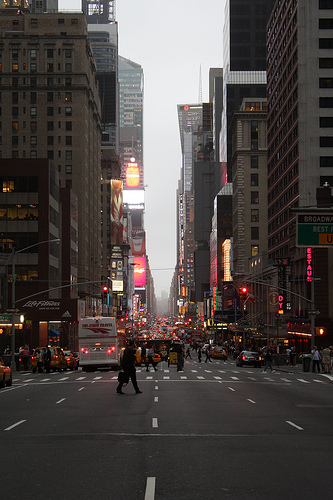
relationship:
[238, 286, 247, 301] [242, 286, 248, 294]
street light with street light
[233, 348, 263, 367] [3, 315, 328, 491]
car on street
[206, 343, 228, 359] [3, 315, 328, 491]
car on street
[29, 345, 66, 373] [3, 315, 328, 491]
car on street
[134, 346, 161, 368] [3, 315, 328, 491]
taxi cab on street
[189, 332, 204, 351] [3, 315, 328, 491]
car on street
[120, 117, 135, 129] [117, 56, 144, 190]
window on building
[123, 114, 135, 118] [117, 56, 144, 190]
window on building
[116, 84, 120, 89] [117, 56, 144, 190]
window on building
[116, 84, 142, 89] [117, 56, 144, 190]
window on building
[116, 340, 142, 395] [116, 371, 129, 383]
person carrying bag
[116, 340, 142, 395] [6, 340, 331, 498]
person crossing street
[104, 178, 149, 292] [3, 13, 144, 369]
billboards on side of buildings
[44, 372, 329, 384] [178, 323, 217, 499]
white marks on street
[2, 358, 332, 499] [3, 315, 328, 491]
lines on street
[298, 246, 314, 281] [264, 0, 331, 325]
sign on building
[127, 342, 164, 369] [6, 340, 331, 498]
taxi cab on street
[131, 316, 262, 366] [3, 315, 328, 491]
traffic in street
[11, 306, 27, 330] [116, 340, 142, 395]
traffic signal for person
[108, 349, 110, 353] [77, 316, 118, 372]
tail light on bus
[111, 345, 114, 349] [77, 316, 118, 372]
tail light on bus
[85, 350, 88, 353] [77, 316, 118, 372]
tail light on bus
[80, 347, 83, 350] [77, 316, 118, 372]
tail light on bus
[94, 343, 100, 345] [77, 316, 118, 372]
tail light on bus